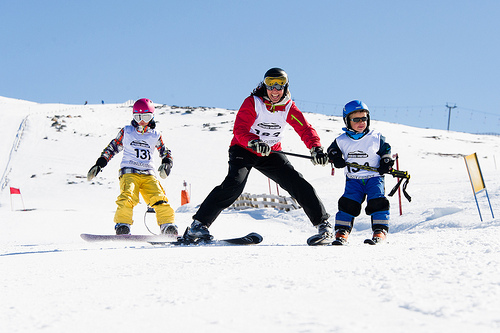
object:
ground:
[4, 97, 485, 332]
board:
[149, 231, 260, 246]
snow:
[0, 97, 498, 329]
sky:
[2, 1, 499, 140]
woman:
[186, 66, 331, 245]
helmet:
[340, 99, 367, 129]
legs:
[190, 145, 254, 240]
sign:
[463, 151, 486, 196]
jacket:
[234, 93, 320, 157]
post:
[445, 110, 452, 130]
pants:
[115, 167, 174, 229]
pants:
[190, 140, 329, 226]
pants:
[333, 175, 392, 231]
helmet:
[131, 99, 157, 122]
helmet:
[264, 67, 289, 90]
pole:
[396, 153, 405, 215]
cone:
[181, 188, 188, 203]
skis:
[80, 233, 187, 243]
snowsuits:
[187, 95, 330, 226]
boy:
[324, 98, 399, 241]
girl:
[89, 97, 182, 233]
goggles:
[132, 112, 155, 125]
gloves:
[87, 165, 106, 180]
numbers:
[137, 151, 146, 160]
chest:
[120, 126, 164, 168]